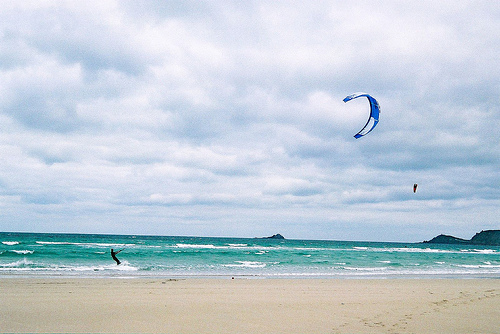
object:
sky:
[0, 1, 499, 244]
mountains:
[427, 233, 469, 243]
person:
[110, 248, 123, 265]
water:
[0, 231, 500, 278]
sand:
[0, 276, 499, 334]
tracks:
[476, 296, 482, 300]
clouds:
[93, 68, 141, 98]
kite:
[343, 91, 381, 140]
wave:
[0, 247, 56, 256]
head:
[111, 248, 114, 252]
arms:
[113, 251, 120, 255]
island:
[266, 233, 285, 239]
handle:
[120, 247, 127, 251]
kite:
[412, 183, 419, 193]